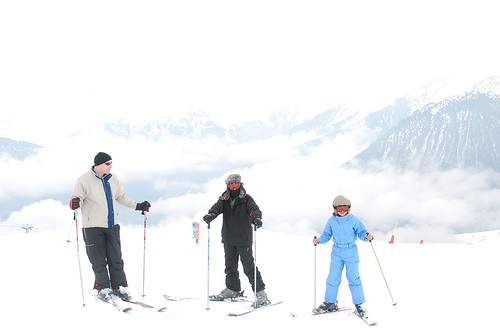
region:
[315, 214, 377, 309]
Child's blue ski outfit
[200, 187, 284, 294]
Person's black ski outfit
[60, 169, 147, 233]
Person's tan ski coat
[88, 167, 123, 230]
Person's blue under shirt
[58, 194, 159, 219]
Person's red and black ski gloves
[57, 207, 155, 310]
Man's red and white ski poles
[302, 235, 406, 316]
Child's black and white ski poles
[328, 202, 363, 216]
Child's black and orange goggles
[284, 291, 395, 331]
Child's set of skis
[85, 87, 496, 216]
Snow capped mountains in the distance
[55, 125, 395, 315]
group of three skiers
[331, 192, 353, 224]
hat on skier's head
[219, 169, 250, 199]
hat on skier's head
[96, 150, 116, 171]
hat on skier's head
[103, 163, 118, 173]
goggles on skier's face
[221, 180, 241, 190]
goggles on skier's face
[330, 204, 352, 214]
goggles on skier's face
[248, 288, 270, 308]
ski boots on person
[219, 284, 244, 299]
ski boots on person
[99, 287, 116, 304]
ski boots on person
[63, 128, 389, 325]
three people about to got skiing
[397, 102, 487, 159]
large blue mountain behind the people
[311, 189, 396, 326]
a kid wearing blue snowsuit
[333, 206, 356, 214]
orange snow google over the eyes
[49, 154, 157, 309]
a man wearing a black ski cap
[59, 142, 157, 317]
a man wearing one red glove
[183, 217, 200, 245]
a blue and pink marker in the snow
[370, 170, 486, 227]
a white cloud behind the people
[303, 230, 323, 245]
a hand holding a ski pole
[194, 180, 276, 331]
a person wearing a black snowsuit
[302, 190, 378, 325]
the person on the right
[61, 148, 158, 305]
the person on the left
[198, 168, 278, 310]
the person in the middle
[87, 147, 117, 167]
the black hat on the man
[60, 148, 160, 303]
the man wearing a black hat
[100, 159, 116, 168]
the sunglasses on the man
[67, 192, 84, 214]
the right hand of the man on the left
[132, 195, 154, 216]
the left hand of the man on the left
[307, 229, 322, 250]
the right hand of the man on the right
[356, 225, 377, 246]
the left hand of the man on the right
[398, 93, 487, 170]
patch of snow on mountain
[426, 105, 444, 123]
patch of snow on mountain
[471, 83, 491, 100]
patch of snow on mountain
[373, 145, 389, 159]
patch of snow on mountain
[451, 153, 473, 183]
patch of snow on mountain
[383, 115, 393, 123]
patch of snow on mountain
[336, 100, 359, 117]
patch of snow on mountain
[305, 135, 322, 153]
patch of snow on mountain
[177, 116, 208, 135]
patch of snow on mountain